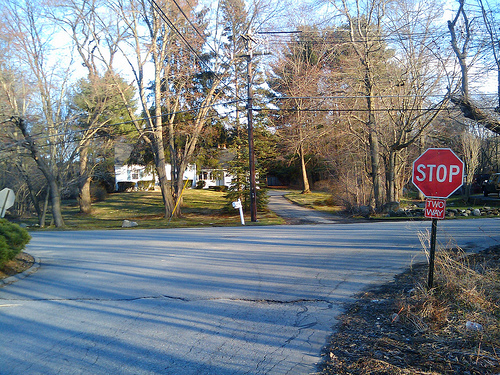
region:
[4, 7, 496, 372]
A street intersection scene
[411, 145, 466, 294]
This is a stop sign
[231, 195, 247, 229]
A residential mailbox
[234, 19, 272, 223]
This is a telephone pole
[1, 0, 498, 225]
Trees are growing across the street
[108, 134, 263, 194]
A house is beyond the trees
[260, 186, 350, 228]
This is a driveway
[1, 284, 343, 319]
A crack is in the street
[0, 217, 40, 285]
A bush is growing on the corner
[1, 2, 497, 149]
Electric lines are above the street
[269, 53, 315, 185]
the trees are bare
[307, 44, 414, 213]
the trees are bare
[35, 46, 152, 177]
the trees are bare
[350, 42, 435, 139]
the trees are bare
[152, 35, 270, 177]
the trees are bare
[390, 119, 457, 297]
a red stop sign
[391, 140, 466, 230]
a red stop sign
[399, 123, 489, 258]
a red stop sign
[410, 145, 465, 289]
sign on side of road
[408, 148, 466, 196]
sign that says stop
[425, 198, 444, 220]
sign that says two way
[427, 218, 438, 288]
pole of sign on road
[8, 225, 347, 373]
road made of concrete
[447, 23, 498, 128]
large tree branch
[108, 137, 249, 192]
white home in wooded area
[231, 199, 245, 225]
white mail box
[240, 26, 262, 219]
power pole in front yard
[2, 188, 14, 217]
back of street sign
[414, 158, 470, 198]
STOP written on sign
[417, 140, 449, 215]
two signs on one pole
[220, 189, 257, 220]
mailbox by the road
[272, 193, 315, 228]
driveway off the road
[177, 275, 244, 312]
crack in the road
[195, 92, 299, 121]
power lines in front of house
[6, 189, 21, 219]
back of the stop sign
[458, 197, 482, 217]
rock wall along the wall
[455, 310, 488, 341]
trash on the ground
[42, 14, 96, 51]
tree is missing leaves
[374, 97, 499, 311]
a stop sign on a pole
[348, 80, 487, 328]
a stop sign on a metal pole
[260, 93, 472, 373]
a stop sign on the side of the road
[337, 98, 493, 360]
a two way stop sign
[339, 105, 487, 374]
a two way sign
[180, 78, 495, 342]
a two way stop sign on the side of the road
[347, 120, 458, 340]
a two way stop sign on a pole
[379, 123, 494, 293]
a two way stop sign on a metal pole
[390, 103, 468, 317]
a pole with a stop sign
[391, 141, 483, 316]
a metal pole with stop sign